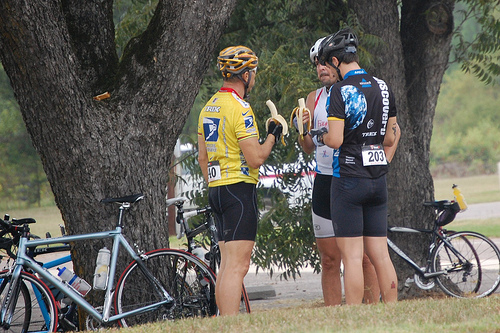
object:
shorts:
[310, 173, 338, 238]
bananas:
[265, 97, 312, 146]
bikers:
[195, 28, 403, 317]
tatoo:
[391, 281, 396, 289]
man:
[198, 44, 283, 316]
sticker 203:
[368, 151, 384, 163]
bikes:
[0, 193, 214, 333]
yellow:
[453, 187, 469, 210]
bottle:
[451, 183, 468, 210]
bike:
[0, 192, 216, 333]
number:
[368, 151, 375, 162]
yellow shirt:
[196, 91, 261, 188]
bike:
[386, 183, 500, 300]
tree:
[337, 0, 466, 303]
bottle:
[56, 266, 90, 295]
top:
[57, 266, 66, 276]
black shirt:
[327, 68, 397, 178]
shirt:
[314, 86, 334, 176]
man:
[312, 27, 398, 305]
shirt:
[198, 86, 260, 188]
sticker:
[208, 167, 216, 178]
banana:
[265, 99, 289, 147]